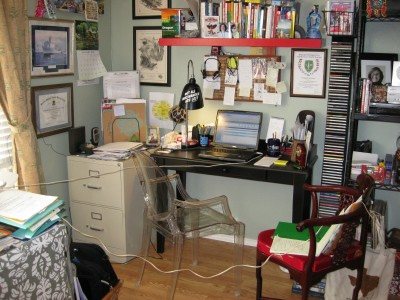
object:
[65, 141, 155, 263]
file cabinet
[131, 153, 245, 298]
chair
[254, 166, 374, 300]
chair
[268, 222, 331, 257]
notebooks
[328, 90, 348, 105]
cd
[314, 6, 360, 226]
column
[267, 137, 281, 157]
cup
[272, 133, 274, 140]
pencils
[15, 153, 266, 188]
wire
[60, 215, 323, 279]
wire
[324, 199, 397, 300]
bag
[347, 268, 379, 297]
texas emblam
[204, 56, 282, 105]
bulletin board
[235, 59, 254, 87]
paper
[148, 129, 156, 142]
photo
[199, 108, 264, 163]
laptop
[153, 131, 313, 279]
desk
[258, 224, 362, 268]
seat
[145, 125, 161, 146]
frame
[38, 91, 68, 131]
diploma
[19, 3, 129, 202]
wall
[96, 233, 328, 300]
floor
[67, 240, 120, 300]
backpack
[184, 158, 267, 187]
drawer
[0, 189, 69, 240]
folders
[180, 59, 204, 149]
lamp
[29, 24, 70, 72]
picture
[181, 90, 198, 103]
letters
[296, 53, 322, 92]
certificate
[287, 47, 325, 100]
frame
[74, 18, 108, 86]
calendar